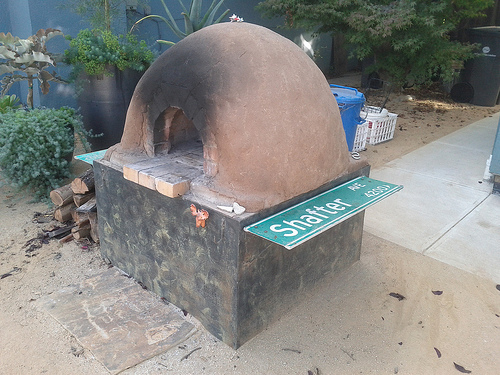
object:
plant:
[128, 0, 248, 46]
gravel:
[21, 325, 48, 375]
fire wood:
[49, 167, 97, 244]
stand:
[94, 158, 371, 349]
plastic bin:
[359, 105, 398, 146]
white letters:
[271, 196, 358, 243]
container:
[75, 60, 152, 154]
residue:
[155, 67, 204, 104]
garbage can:
[443, 25, 500, 106]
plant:
[0, 104, 104, 206]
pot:
[76, 59, 151, 152]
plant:
[62, 17, 159, 84]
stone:
[34, 266, 201, 375]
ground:
[381, 157, 498, 349]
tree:
[252, 0, 492, 90]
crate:
[350, 120, 369, 153]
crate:
[359, 105, 397, 146]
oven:
[91, 20, 371, 348]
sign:
[243, 176, 403, 253]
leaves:
[384, 279, 471, 372]